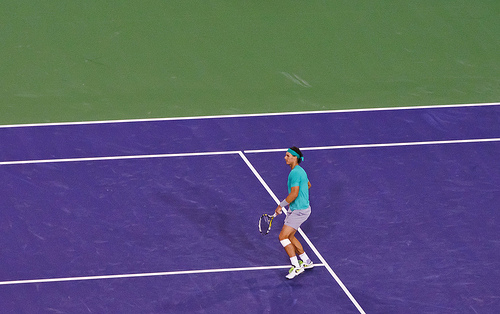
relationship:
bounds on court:
[0, 2, 497, 121] [2, 1, 495, 309]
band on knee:
[280, 238, 291, 247] [278, 230, 290, 243]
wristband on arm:
[278, 205, 288, 212] [279, 180, 291, 206]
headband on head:
[283, 145, 301, 158] [275, 141, 310, 171]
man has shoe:
[275, 146, 314, 279] [285, 260, 313, 280]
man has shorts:
[275, 146, 314, 279] [281, 201, 317, 231]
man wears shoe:
[271, 147, 320, 279] [282, 255, 300, 280]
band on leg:
[278, 237, 290, 245] [277, 220, 302, 265]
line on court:
[2, 99, 498, 130] [1, 97, 498, 311]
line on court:
[1, 134, 499, 166] [1, 97, 498, 311]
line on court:
[0, 258, 325, 293] [1, 97, 498, 311]